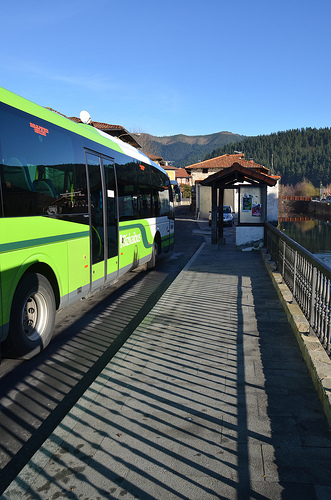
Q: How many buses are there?
A: One.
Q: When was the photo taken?
A: During the day.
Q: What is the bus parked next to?
A: The sidewalk.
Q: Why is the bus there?
A: To pick up passengers.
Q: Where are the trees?
A: Behind the buildings.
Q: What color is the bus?
A: Green.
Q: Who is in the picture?
A: Nobody.